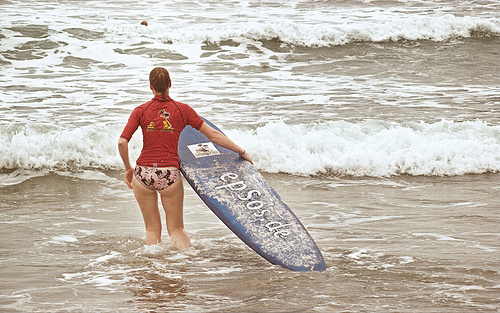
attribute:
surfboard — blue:
[168, 114, 328, 274]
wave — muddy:
[108, 14, 499, 60]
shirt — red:
[120, 95, 205, 168]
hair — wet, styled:
[147, 66, 172, 102]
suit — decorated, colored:
[132, 162, 182, 189]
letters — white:
[217, 168, 291, 239]